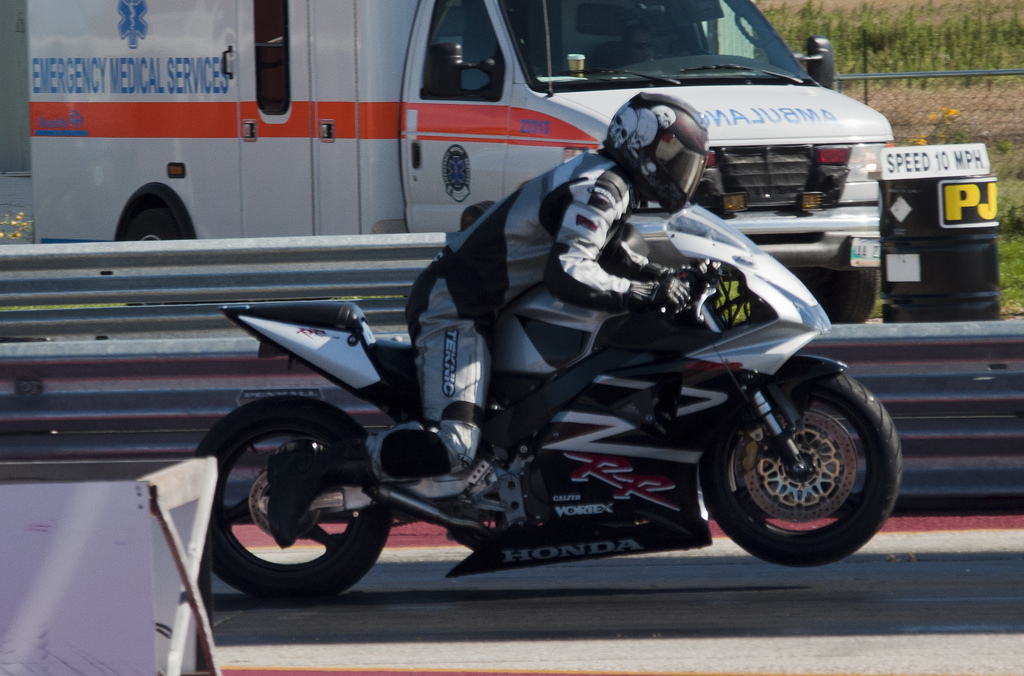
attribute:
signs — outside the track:
[867, 137, 1002, 192]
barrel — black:
[884, 161, 1012, 317]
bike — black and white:
[196, 202, 899, 604]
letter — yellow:
[944, 185, 975, 224]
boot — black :
[233, 436, 376, 543]